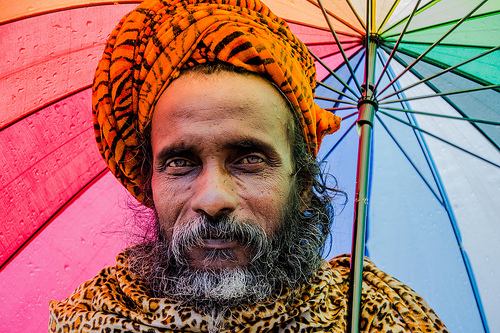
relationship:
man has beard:
[108, 72, 323, 289] [168, 220, 304, 296]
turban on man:
[147, 6, 263, 62] [108, 72, 323, 289]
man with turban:
[108, 72, 323, 289] [147, 6, 263, 62]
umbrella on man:
[17, 28, 88, 209] [108, 72, 323, 289]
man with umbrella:
[108, 72, 323, 289] [17, 28, 88, 209]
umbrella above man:
[17, 28, 88, 209] [108, 72, 323, 289]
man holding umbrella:
[108, 72, 323, 289] [17, 28, 88, 209]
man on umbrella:
[108, 72, 323, 289] [17, 28, 88, 209]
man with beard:
[108, 72, 323, 289] [168, 220, 304, 296]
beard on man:
[168, 220, 304, 296] [108, 72, 323, 289]